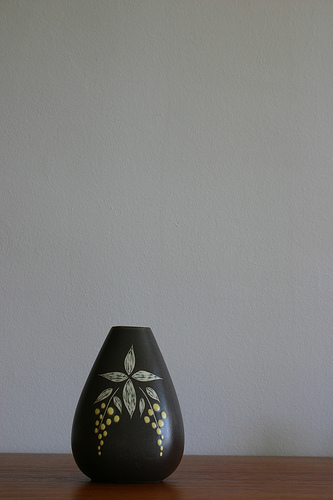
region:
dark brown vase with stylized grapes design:
[70, 325, 184, 482]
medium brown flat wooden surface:
[0, 452, 332, 498]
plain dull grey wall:
[0, 1, 331, 457]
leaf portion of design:
[92, 344, 161, 418]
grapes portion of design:
[93, 402, 165, 456]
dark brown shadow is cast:
[72, 480, 180, 499]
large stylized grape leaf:
[121, 378, 136, 417]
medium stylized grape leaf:
[96, 371, 127, 381]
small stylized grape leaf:
[138, 397, 144, 416]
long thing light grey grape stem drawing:
[137, 386, 159, 439]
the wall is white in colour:
[79, 166, 197, 254]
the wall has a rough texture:
[157, 256, 295, 359]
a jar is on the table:
[66, 304, 200, 485]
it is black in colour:
[58, 302, 194, 481]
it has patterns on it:
[69, 337, 176, 450]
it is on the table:
[63, 291, 213, 499]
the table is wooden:
[184, 459, 250, 491]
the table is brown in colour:
[204, 448, 288, 498]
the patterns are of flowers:
[94, 345, 153, 417]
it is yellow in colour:
[131, 380, 176, 453]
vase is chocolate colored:
[71, 323, 186, 485]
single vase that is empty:
[71, 325, 186, 484]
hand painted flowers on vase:
[91, 345, 167, 458]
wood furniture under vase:
[0, 453, 330, 499]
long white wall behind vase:
[0, 1, 332, 452]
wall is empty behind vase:
[0, 0, 332, 456]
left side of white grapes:
[91, 404, 120, 457]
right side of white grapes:
[143, 402, 167, 456]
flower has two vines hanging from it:
[92, 344, 166, 458]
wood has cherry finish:
[0, 452, 332, 498]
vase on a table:
[41, 292, 208, 490]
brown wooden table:
[193, 454, 315, 499]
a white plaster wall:
[6, 3, 332, 193]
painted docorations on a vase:
[75, 341, 175, 466]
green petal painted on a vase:
[119, 347, 138, 372]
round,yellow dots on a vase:
[154, 436, 165, 457]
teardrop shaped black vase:
[51, 298, 202, 483]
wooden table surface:
[1, 451, 327, 499]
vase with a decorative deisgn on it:
[83, 345, 172, 462]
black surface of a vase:
[116, 445, 144, 467]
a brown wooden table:
[1, 451, 332, 499]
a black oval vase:
[68, 323, 186, 484]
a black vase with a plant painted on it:
[69, 326, 186, 483]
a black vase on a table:
[0, 324, 329, 498]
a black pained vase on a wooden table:
[1, 325, 332, 498]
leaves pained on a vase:
[94, 345, 163, 419]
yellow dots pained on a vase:
[90, 399, 168, 460]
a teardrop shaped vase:
[70, 322, 185, 485]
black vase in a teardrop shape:
[72, 324, 185, 483]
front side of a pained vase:
[71, 325, 186, 481]